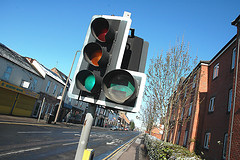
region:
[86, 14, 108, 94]
street signal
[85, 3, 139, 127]
traffic signal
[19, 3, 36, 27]
white clouds in blue sky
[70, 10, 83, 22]
white clouds in blue sky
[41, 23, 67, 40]
white clouds in blue sky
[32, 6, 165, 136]
a traffic light on the street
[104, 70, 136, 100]
a green arrow on the traffic light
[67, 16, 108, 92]
a traffic light has red, yellow and green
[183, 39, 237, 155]
a building along the street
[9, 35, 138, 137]
this side of the street has buildings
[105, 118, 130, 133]
parked cars in the area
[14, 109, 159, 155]
this is a long block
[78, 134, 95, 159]
a yellow stop walk button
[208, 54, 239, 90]
windows in a building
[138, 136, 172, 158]
bushes near the building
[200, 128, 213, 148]
window on large building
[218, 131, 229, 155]
window on large building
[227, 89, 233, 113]
window on large building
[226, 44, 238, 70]
window on large building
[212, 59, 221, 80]
window on large building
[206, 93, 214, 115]
window on large building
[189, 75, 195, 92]
window on large building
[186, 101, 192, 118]
window on large building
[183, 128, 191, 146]
window on large building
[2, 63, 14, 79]
window on large building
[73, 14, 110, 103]
black traffic signal on pole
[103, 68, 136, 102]
green arrow on traffic signal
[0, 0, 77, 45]
the clear blue sky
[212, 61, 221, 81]
window on building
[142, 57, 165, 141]
trees on the land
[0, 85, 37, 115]
yellow building on pavement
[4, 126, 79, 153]
white lines painted on street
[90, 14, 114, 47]
red light on traffic signal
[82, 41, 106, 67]
yellow light on traffic signal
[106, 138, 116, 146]
arrow painted in the street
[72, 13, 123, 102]
signal light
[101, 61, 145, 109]
green signal light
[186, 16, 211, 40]
white clouds in blue sky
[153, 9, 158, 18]
white clouds in blue sky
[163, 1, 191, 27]
white clouds in blue sky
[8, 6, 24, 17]
white clouds in blue sky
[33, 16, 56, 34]
white clouds in blue sky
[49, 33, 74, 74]
white clouds in blue sky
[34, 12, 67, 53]
white clouds in blue sky